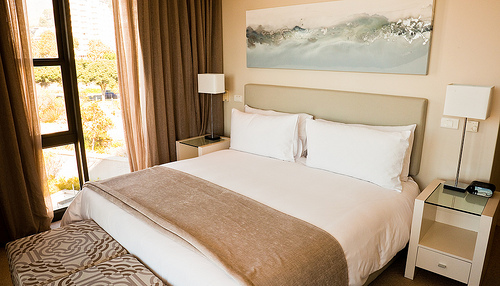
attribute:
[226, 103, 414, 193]
pillows — white, four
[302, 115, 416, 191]
pillows — white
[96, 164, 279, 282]
bedspread — brown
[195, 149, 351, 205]
cover — white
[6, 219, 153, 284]
seat — brown and white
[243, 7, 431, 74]
painting — brown and tan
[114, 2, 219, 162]
coverings — tan, window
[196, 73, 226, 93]
lamp shade — white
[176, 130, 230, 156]
night stand — tan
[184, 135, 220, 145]
table top — glass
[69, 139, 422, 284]
comforter — white